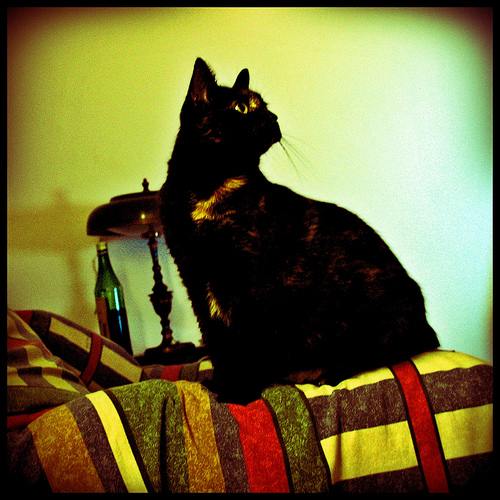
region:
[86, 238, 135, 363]
tall green glass bottle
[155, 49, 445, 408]
black and orange house cat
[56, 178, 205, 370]
dark brown table lamp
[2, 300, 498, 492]
green, brown, orange, red, and white blanket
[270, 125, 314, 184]
thin black cat whiskers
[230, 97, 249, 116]
pretty yellow cat eye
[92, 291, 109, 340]
red label on a green bottle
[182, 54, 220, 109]
furry black cat ear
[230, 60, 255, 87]
furry black cat ear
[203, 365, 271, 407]
black cat's front paws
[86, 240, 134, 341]
bottle of red wine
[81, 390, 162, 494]
white diagonal stripe and black diagonal stripe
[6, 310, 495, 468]
a chair covered in a blanket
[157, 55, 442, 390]
a black house cat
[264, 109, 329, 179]
a cat's black whiskers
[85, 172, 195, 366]
a tableside lamp with a glass shade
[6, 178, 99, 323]
a shadow on the wall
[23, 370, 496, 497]
chenille multicolored striped blanket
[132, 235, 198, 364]
a cast iron lamp base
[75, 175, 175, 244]
a dark colored glass lamp shade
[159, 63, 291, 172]
the head of a cat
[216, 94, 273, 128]
the eye of a cat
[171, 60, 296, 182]
the ears of a cat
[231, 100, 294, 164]
the nose of a cat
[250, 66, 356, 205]
the whiskers of a cat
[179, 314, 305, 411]
the paw of a cat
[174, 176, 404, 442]
the body of a cat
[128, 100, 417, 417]
a cat on a couch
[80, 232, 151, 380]
a bottle near a cat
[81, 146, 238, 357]
a lamp near a couch